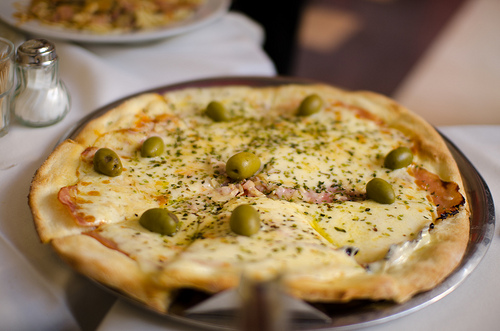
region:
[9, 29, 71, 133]
glass salt shaker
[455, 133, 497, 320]
metal pizza pan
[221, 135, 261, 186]
green olive on pizza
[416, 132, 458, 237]
ham on the edge of the pizza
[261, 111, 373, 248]
melted cheese on top of pizza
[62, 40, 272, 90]
white tablecloth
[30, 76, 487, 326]
pizza on a pizza pan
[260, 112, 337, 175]
green herbs sprinkled on top of cheese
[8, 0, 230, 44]
plate full of food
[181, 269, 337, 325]
metal spatula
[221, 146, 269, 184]
A green olive on a pizza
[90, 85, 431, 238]
Nine green olives on cheese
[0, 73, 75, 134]
Salt in a shaker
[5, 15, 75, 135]
A glass salt shaker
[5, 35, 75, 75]
A metal salt shaker top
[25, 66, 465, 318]
A personal size pizza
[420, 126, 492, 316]
A metal serving pan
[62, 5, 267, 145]
A white table cloth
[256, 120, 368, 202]
Oregano sprinkled on cheese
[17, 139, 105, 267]
Browned pizza crust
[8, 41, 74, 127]
A small shaker of salt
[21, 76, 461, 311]
A small pizza pie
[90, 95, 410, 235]
A handful of whole green olives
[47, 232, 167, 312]
Pizza crust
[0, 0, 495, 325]
A pizza bistro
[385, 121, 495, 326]
The edge of a silver platter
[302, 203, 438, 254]
Melted cheese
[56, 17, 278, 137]
An elegant white tablecloth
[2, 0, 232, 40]
A plate of food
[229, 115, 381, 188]
Green seasoning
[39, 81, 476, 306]
a small pizza with cheese and green olives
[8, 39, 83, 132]
a salt shaker on the table next to the pizza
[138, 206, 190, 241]
a green olive on the pizza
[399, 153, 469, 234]
a sauce splodge on the pizza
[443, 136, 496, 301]
the edge of the silver tray the pizza is on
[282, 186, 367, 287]
a slice mark in the cheese of the pizza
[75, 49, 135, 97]
the white table cloth that is covering the table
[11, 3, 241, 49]
another Italian dish served on the same table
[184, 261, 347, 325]
a spatula used to serve the pizza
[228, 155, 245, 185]
a hole in one of the green olives on the pizza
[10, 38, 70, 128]
a salt shaker sitting on a table.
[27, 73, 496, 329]
A small pizza with green olives.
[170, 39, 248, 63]
white table cloth on table.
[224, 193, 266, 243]
Green pepper on top of the pizza.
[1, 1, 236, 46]
Plate of food.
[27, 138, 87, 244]
Pizza crust.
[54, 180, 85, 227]
Meat on the pizza.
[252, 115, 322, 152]
Seasoning on the pizza.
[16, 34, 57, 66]
Metal top on top of salt shaker.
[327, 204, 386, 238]
Cheese on pizza.